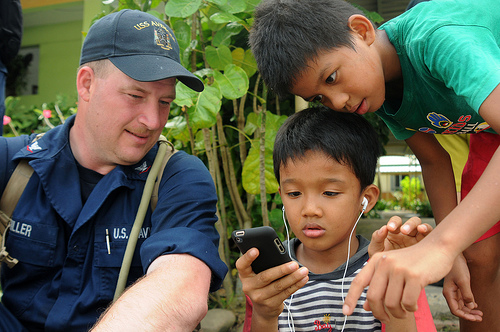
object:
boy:
[233, 105, 436, 331]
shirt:
[242, 235, 441, 332]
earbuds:
[358, 195, 368, 213]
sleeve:
[139, 151, 231, 294]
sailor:
[0, 8, 230, 331]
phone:
[230, 224, 293, 274]